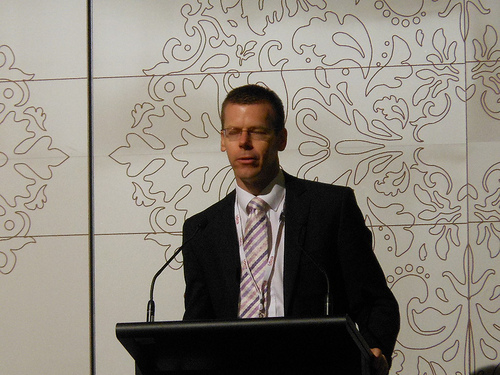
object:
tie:
[239, 198, 270, 316]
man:
[177, 83, 400, 373]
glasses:
[221, 124, 277, 138]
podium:
[107, 312, 389, 373]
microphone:
[147, 216, 212, 319]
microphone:
[295, 217, 333, 318]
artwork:
[108, 1, 499, 374]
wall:
[0, 0, 498, 375]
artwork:
[0, 45, 70, 276]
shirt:
[235, 172, 285, 318]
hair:
[221, 85, 284, 130]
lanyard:
[234, 191, 285, 316]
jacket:
[170, 169, 400, 368]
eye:
[251, 127, 266, 136]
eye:
[220, 127, 241, 137]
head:
[218, 85, 287, 194]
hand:
[371, 347, 391, 374]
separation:
[86, 1, 96, 374]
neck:
[236, 176, 286, 218]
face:
[216, 102, 291, 180]